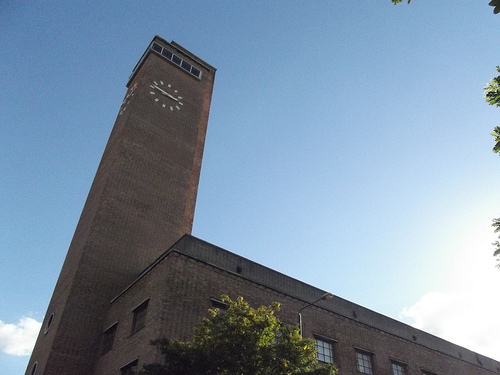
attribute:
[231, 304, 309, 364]
leaves — green 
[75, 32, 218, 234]
tower — tall, brick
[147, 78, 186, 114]
display — 3:50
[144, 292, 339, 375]
tree — leafy, green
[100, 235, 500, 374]
building — brick , clock tower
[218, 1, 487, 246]
sky — clear, blue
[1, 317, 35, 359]
cloud — white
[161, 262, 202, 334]
bricks — red, brown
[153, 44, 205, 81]
window — rectangular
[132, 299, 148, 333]
windows — glass, small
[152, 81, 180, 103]
clock hands — white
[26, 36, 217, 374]
tower — tall